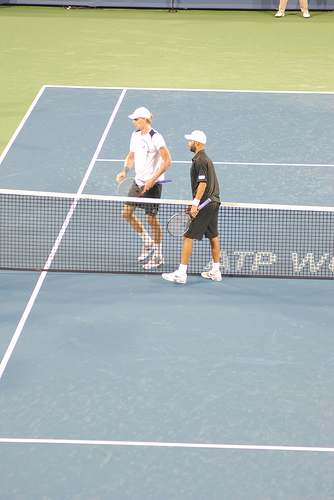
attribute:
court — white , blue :
[0, 9, 332, 499]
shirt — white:
[125, 130, 165, 189]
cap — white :
[126, 103, 155, 122]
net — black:
[1, 188, 333, 281]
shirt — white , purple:
[127, 129, 166, 182]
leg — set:
[273, 1, 289, 20]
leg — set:
[295, 0, 312, 19]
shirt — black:
[184, 145, 221, 207]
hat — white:
[180, 126, 210, 145]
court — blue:
[1, 84, 331, 499]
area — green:
[66, 8, 312, 103]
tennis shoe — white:
[156, 266, 191, 286]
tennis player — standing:
[156, 127, 229, 289]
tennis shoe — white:
[197, 267, 224, 281]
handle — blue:
[155, 174, 174, 185]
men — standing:
[175, 114, 231, 308]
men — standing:
[105, 82, 163, 268]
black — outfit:
[192, 153, 220, 239]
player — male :
[116, 105, 172, 269]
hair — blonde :
[144, 112, 152, 124]